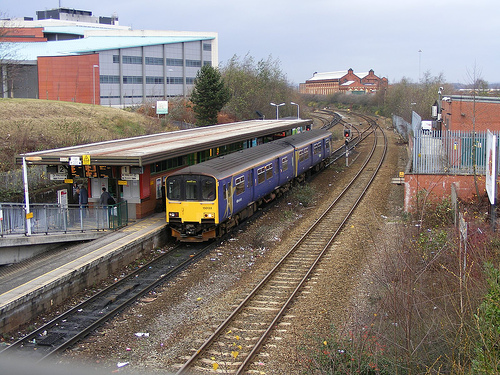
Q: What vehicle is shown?
A: Train.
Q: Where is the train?
A: Station.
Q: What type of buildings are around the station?
A: Brick.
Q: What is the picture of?
A: A train and railway tracks.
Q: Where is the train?
A: At a railway station.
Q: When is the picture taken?
A: During daytime.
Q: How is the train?
A: Blue colored with yellow front, and it is short.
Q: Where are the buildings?
A: On both sides of the track and also in the background.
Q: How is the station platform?
A: Long and narrow.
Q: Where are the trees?
A: On both sides of the tracks.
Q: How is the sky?
A: Clear blue.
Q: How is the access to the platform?
A: Sloping ramp and no stairs.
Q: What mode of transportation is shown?
A: Train.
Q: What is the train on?
A: Tracks.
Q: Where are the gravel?
A: Between the tracks.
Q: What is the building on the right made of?
A: Brick.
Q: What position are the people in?
A: Standing.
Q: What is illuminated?
A: Traffic control lights.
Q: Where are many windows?
A: Buildings.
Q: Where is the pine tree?
A: Small bank behind the train station.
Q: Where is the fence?
A: Beside the buildings.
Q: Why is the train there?
A: Transport.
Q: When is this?
A: Afternoon.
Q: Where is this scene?
A: Train station.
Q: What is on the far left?
A: Building.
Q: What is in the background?
A: Trees.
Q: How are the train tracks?
A: Old.